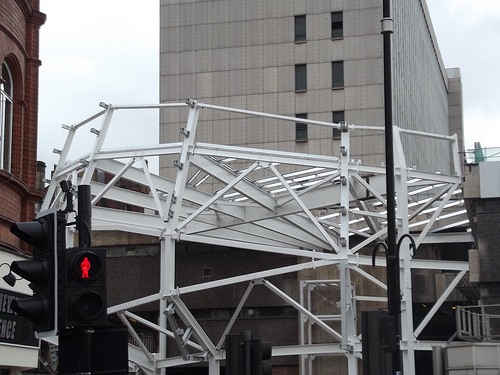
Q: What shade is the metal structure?
A: White.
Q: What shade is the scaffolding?
A: White.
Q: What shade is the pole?
A: White.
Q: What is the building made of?
A: Bricks.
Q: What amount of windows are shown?
A: Six.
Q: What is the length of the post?
A: Tall.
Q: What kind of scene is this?
A: Commercial.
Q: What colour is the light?
A: Red.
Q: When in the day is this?
A: Afternoon.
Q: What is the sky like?
A: Cloudy.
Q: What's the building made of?
A: Steel.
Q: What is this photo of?
A: A building.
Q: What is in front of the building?
A: A light pole.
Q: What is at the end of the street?
A: A stop light.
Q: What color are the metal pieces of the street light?
A: Black.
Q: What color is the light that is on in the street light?
A: Red.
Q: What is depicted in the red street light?
A: Person.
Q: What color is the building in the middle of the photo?
A: Gray.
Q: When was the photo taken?
A: Daytime.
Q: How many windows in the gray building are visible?
A: Six.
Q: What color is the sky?
A: White.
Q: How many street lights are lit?
A: One.